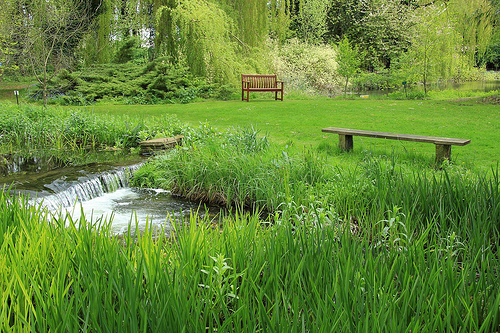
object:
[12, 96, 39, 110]
pole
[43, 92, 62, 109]
ground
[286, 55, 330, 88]
bush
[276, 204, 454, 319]
grass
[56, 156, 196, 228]
pond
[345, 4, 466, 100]
bush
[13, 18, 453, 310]
park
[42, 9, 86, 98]
tree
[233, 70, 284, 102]
bench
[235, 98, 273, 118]
grass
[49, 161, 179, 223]
pond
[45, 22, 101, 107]
tree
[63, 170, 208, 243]
pond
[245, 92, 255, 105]
leg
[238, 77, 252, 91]
armrest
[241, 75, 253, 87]
arm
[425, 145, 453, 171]
blocks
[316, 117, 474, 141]
board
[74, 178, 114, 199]
waterfall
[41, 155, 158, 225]
creek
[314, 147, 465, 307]
weeds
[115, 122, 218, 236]
creek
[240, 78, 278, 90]
back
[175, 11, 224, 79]
willows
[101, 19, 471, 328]
property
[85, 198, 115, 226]
foam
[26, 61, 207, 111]
shrubs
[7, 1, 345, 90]
trees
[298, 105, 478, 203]
bench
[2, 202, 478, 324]
outside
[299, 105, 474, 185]
bench